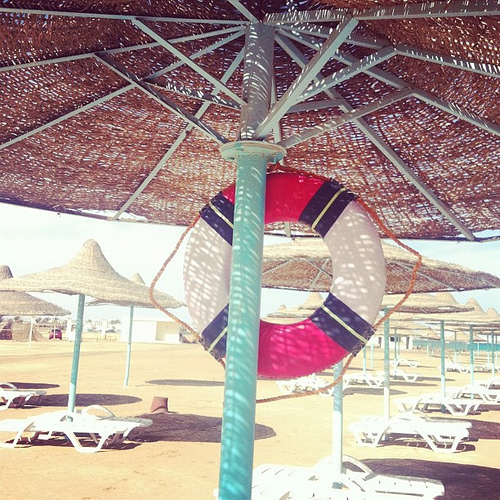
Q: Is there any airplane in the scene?
A: No, there are no airplanes.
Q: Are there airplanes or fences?
A: No, there are no airplanes or fences.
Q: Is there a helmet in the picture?
A: No, there are no helmets.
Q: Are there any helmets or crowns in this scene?
A: No, there are no helmets or crowns.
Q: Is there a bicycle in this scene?
A: No, there are no bicycles.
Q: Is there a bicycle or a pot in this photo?
A: No, there are no bicycles or pots.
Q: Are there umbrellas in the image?
A: Yes, there is an umbrella.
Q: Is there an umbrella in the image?
A: Yes, there is an umbrella.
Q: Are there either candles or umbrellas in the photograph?
A: Yes, there is an umbrella.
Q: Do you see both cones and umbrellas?
A: No, there is an umbrella but no cones.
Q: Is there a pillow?
A: No, there are no pillows.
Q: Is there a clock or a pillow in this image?
A: No, there are no pillows or clocks.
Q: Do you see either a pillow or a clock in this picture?
A: No, there are no pillows or clocks.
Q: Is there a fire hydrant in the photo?
A: No, there are no fire hydrants.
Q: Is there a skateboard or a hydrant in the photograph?
A: No, there are no fire hydrants or skateboards.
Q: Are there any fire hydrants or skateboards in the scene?
A: No, there are no fire hydrants or skateboards.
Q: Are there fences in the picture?
A: No, there are no fences.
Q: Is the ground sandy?
A: Yes, the ground is sandy.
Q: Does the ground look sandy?
A: Yes, the ground is sandy.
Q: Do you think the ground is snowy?
A: No, the ground is sandy.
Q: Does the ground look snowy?
A: No, the ground is sandy.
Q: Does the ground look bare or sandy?
A: The ground is sandy.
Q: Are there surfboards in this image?
A: No, there are no surfboards.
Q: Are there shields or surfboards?
A: No, there are no surfboards or shields.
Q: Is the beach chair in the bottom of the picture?
A: Yes, the beach chair is in the bottom of the image.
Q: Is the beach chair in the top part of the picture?
A: No, the beach chair is in the bottom of the image.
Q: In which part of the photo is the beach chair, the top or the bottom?
A: The beach chair is in the bottom of the image.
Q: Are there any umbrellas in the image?
A: Yes, there is an umbrella.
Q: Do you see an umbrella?
A: Yes, there is an umbrella.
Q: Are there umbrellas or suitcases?
A: Yes, there is an umbrella.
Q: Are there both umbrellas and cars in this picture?
A: Yes, there are both an umbrella and a car.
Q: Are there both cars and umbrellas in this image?
A: Yes, there are both an umbrella and a car.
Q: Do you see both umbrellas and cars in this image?
A: Yes, there are both an umbrella and a car.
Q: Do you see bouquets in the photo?
A: No, there are no bouquets.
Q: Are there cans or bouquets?
A: No, there are no bouquets or cans.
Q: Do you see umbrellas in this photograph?
A: Yes, there is an umbrella.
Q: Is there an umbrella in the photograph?
A: Yes, there is an umbrella.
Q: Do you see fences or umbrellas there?
A: Yes, there is an umbrella.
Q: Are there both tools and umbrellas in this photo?
A: No, there is an umbrella but no tools.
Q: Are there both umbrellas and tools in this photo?
A: No, there is an umbrella but no tools.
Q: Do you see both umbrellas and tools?
A: No, there is an umbrella but no tools.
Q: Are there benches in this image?
A: No, there are no benches.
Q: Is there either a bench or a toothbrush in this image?
A: No, there are no benches or toothbrushes.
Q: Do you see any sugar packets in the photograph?
A: No, there are no sugar packets.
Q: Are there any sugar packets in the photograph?
A: No, there are no sugar packets.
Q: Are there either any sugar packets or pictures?
A: No, there are no sugar packets or pictures.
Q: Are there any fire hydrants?
A: No, there are no fire hydrants.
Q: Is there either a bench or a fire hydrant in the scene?
A: No, there are no fire hydrants or benches.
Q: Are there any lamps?
A: No, there are no lamps.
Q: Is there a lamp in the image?
A: No, there are no lamps.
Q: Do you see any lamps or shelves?
A: No, there are no lamps or shelves.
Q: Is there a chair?
A: Yes, there is a chair.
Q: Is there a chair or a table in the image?
A: Yes, there is a chair.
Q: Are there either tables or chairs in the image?
A: Yes, there is a chair.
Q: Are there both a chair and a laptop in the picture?
A: No, there is a chair but no laptops.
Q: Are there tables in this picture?
A: No, there are no tables.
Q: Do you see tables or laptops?
A: No, there are no tables or laptops.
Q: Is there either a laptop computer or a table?
A: No, there are no tables or laptops.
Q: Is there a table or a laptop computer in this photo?
A: No, there are no tables or laptops.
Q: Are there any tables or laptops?
A: No, there are no tables or laptops.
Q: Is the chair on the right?
A: Yes, the chair is on the right of the image.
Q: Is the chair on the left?
A: No, the chair is on the right of the image.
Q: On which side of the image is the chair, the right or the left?
A: The chair is on the right of the image.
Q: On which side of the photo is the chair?
A: The chair is on the right of the image.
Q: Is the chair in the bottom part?
A: Yes, the chair is in the bottom of the image.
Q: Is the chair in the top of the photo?
A: No, the chair is in the bottom of the image.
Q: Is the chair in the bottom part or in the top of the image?
A: The chair is in the bottom of the image.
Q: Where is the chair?
A: The chair is at the ground.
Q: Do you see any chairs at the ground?
A: Yes, there is a chair at the ground.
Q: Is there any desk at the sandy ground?
A: No, there is a chair at the ground.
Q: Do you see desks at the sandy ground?
A: No, there is a chair at the ground.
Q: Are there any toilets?
A: No, there are no toilets.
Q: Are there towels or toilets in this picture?
A: No, there are no toilets or towels.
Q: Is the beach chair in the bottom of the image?
A: Yes, the beach chair is in the bottom of the image.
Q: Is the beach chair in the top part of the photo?
A: No, the beach chair is in the bottom of the image.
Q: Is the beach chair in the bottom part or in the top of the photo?
A: The beach chair is in the bottom of the image.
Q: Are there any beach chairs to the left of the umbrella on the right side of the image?
A: Yes, there is a beach chair to the left of the umbrella.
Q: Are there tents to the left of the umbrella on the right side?
A: No, there is a beach chair to the left of the umbrella.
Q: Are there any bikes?
A: No, there are no bikes.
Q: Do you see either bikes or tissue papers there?
A: No, there are no bikes or tissue papers.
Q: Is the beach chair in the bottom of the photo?
A: Yes, the beach chair is in the bottom of the image.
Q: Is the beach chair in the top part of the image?
A: No, the beach chair is in the bottom of the image.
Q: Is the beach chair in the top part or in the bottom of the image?
A: The beach chair is in the bottom of the image.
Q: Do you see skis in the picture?
A: No, there are no skis.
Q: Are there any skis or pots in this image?
A: No, there are no skis or pots.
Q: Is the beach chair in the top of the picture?
A: No, the beach chair is in the bottom of the image.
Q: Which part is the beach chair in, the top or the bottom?
A: The beach chair is in the bottom of the image.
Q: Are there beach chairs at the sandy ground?
A: Yes, there is a beach chair at the ground.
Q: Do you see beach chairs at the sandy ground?
A: Yes, there is a beach chair at the ground.